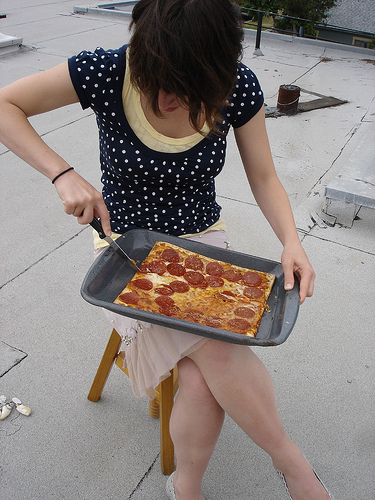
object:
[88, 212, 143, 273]
holding knife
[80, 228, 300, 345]
pan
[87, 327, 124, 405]
wood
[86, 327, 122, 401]
leg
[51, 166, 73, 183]
bracelet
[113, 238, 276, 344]
cheese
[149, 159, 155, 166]
polkadots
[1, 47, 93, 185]
girl's arm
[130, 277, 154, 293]
pepperoni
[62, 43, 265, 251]
shirt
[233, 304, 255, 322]
pepperoni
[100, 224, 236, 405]
skirt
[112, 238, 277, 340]
pizza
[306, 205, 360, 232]
road cracks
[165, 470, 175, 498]
heel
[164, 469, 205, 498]
shoe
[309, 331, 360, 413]
cement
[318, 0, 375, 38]
sidewalk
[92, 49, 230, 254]
undershirt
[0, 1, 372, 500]
road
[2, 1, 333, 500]
girl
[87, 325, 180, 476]
chair